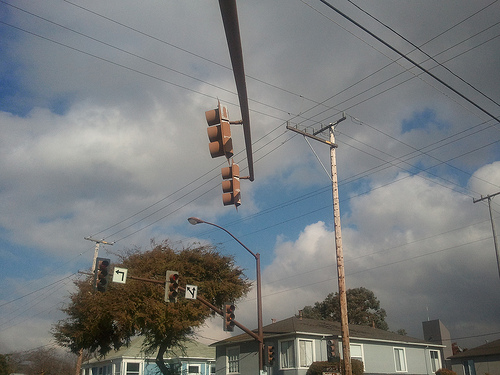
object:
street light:
[186, 216, 267, 375]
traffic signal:
[164, 270, 179, 304]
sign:
[112, 266, 128, 284]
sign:
[184, 284, 198, 299]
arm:
[93, 257, 260, 340]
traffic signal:
[95, 257, 110, 293]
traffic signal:
[223, 302, 236, 331]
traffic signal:
[262, 345, 276, 368]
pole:
[256, 253, 265, 375]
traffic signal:
[204, 99, 234, 159]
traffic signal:
[221, 158, 242, 209]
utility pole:
[286, 115, 353, 374]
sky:
[0, 1, 499, 189]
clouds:
[191, 162, 499, 349]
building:
[422, 319, 454, 368]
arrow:
[115, 270, 124, 281]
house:
[207, 309, 450, 375]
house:
[80, 324, 219, 375]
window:
[391, 347, 409, 374]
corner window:
[277, 330, 329, 370]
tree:
[49, 240, 256, 374]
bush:
[307, 359, 364, 374]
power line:
[320, 0, 500, 123]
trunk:
[155, 339, 175, 375]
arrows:
[186, 287, 195, 299]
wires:
[1, 0, 500, 327]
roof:
[207, 310, 446, 347]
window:
[122, 359, 143, 375]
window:
[185, 364, 200, 374]